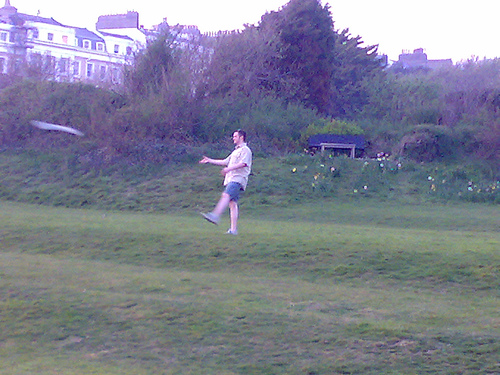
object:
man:
[198, 130, 251, 235]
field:
[1, 197, 499, 371]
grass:
[4, 72, 498, 373]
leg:
[228, 195, 237, 227]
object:
[32, 121, 81, 138]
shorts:
[226, 183, 242, 204]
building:
[1, 1, 218, 90]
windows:
[30, 29, 70, 45]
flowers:
[290, 147, 497, 193]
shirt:
[222, 142, 252, 192]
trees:
[137, 1, 387, 122]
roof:
[0, 5, 206, 47]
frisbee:
[26, 119, 83, 139]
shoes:
[201, 212, 221, 229]